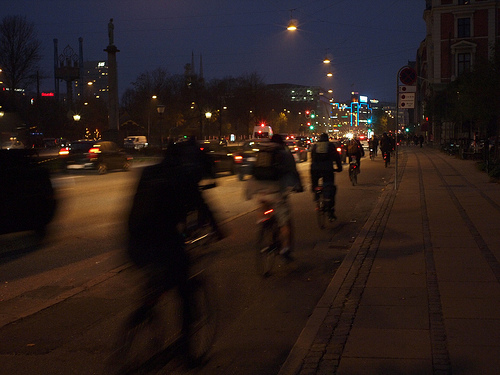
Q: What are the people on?
A: Road bikes.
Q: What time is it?
A: Night.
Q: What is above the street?
A: Lights.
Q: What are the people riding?
A: Bikes.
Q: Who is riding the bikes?
A: The people.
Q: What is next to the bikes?
A: Buildings.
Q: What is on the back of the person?
A: Backpack.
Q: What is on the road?
A: Cars.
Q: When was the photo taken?
A: Night.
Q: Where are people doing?
A: Riding bicycles.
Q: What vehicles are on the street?
A: Cars and bicycles.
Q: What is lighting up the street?
A: Street Lights.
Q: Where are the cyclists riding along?
A: A curbside.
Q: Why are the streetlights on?
A: It is nighttime.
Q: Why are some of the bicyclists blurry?
A: They are in motion.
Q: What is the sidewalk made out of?
A: Tiles and concrete.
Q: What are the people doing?
A: Riding bikes.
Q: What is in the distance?
A: Buildings.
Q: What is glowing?
A: Lights from the buildings.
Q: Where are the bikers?
A: On a street.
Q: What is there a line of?
A: Bikers.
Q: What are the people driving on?
A: A bike lane.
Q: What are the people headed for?
A: The city.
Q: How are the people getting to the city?
A: Bikes.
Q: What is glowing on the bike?
A: A reflector.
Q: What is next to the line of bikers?
A: Vehicles.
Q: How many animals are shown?
A: 0.